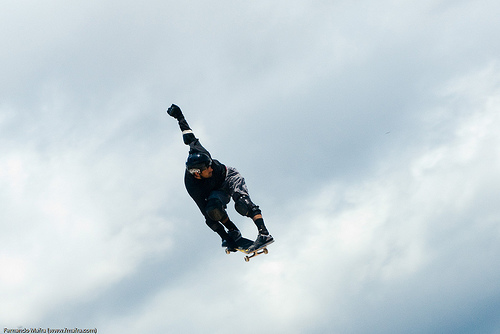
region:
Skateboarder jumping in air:
[166, 102, 274, 261]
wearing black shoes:
[247, 233, 278, 252]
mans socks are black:
[250, 213, 271, 243]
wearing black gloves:
[165, 98, 187, 138]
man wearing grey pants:
[220, 167, 258, 218]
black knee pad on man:
[231, 195, 254, 215]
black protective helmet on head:
[183, 151, 214, 181]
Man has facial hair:
[180, 147, 220, 183]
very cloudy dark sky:
[308, 48, 486, 329]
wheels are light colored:
[241, 250, 269, 265]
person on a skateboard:
[129, 88, 290, 274]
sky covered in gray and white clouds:
[1, 3, 496, 332]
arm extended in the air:
[162, 96, 200, 142]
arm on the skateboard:
[207, 198, 249, 252]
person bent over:
[151, 100, 278, 255]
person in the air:
[147, 71, 316, 291]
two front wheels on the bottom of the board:
[242, 243, 275, 263]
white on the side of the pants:
[225, 163, 247, 197]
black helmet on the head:
[179, 146, 221, 186]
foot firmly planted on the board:
[239, 230, 280, 255]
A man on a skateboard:
[165, 102, 277, 260]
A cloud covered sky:
[9, 5, 499, 325]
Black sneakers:
[215, 227, 276, 254]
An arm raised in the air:
[164, 102, 214, 162]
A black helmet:
[185, 150, 213, 171]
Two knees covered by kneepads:
[202, 198, 259, 220]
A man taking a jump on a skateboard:
[165, 101, 276, 263]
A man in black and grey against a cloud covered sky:
[7, 7, 498, 322]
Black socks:
[222, 215, 272, 233]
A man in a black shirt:
[165, 100, 275, 264]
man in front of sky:
[165, 103, 274, 263]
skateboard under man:
[227, 235, 274, 260]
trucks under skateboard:
[245, 249, 272, 259]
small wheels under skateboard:
[242, 255, 252, 263]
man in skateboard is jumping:
[166, 102, 273, 262]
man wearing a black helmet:
[186, 152, 211, 182]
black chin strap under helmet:
[195, 170, 204, 181]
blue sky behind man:
[0, 0, 497, 332]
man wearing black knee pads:
[234, 195, 251, 216]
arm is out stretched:
[167, 102, 202, 149]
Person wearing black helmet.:
[183, 142, 221, 188]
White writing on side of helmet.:
[183, 163, 205, 176]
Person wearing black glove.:
[159, 96, 191, 129]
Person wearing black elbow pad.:
[174, 123, 197, 145]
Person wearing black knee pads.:
[202, 202, 252, 217]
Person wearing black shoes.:
[217, 225, 271, 260]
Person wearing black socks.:
[242, 217, 289, 249]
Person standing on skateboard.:
[203, 210, 265, 273]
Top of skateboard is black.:
[216, 215, 286, 296]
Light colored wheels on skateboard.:
[205, 237, 312, 282]